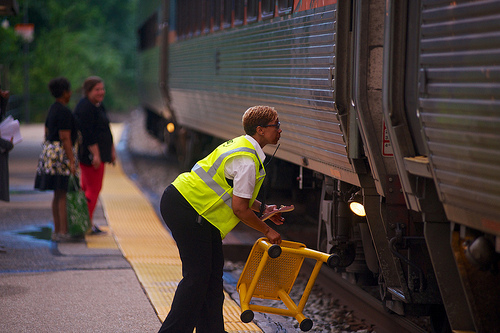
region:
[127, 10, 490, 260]
a train on the tracks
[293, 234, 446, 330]
the train tracks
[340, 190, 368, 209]
a light on the train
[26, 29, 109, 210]
people standing next to the train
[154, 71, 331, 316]
a person wearing a yellow vest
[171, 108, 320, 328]
a person holding a yellow stool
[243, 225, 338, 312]
a yellow stool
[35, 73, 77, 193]
a person wearing a dress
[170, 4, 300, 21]
windows on the train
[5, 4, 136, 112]
trees behind the train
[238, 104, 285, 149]
Woman wearing eye glasses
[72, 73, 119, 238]
Woman wearing red pants and blue sweater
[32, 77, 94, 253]
Woman wearing a patterned black and white skirt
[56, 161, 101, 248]
Green shopping bag in woman's right hand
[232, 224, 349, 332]
Woman holding yellow step stool in right hand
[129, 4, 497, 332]
Passenger train parked at train station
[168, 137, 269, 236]
Train station worker's fluorescent yellow vest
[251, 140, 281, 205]
Worker's walkie talkie in front of shirt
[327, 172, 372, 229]
Light on bottom of train near stairs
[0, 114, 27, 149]
Person holding white papers in right hand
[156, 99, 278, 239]
one woman wearing yellow fluorescent vest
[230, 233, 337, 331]
bottom of yellow metal stool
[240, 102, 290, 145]
woman with short brown hair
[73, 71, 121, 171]
one lady wearing dark shirt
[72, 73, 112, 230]
lady wearing red pants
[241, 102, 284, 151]
one woman with dark framed glasses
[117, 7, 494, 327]
silver passenger train at platform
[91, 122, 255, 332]
section of yellow textured pavement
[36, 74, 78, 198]
one woman wearing patterned skirt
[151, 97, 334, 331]
one woman picking up stool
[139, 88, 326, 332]
the woman beside the train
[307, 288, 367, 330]
gravel beside the tracks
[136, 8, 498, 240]
the train on the tracks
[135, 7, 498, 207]
the train at the platform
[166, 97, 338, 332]
the woman holding the stool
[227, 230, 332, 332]
the stool is yellow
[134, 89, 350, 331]
the woman is crouching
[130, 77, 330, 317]
the woman wearing the safety jacket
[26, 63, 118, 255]
passengers on the platform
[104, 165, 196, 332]
yellow line on the platform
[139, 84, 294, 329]
woman inspecting the train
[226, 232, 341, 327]
yellow stool the woman is holding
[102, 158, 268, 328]
yellow striped painted on the platform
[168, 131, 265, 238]
yellow and gray safety vest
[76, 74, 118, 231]
woman wearing red pants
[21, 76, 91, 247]
woman wearing dress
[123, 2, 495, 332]
train stopped beside the platform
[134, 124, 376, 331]
gravel around the train tracks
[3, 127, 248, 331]
platform next to the train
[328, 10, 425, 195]
door to the train car